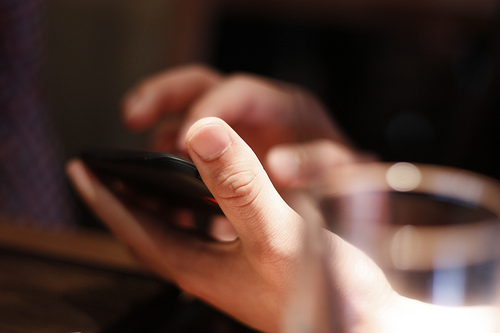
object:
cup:
[283, 159, 497, 329]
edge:
[286, 159, 499, 266]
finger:
[168, 112, 351, 310]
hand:
[62, 115, 499, 332]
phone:
[80, 145, 236, 236]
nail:
[187, 125, 233, 157]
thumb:
[175, 108, 326, 266]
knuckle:
[235, 227, 343, 273]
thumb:
[166, 100, 282, 220]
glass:
[284, 145, 499, 313]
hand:
[48, 106, 498, 332]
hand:
[47, 112, 500, 331]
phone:
[83, 138, 234, 232]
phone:
[82, 127, 252, 240]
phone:
[67, 145, 240, 245]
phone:
[84, 151, 223, 220]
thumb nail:
[185, 127, 235, 161]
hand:
[62, 117, 489, 332]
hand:
[48, 112, 495, 332]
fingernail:
[187, 122, 233, 156]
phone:
[80, 142, 224, 221]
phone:
[81, 122, 241, 251]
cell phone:
[68, 131, 251, 218]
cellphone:
[76, 132, 248, 228]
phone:
[65, 118, 235, 229]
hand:
[57, 115, 482, 332]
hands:
[65, 112, 499, 331]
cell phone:
[63, 127, 253, 252]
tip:
[61, 158, 88, 181]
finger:
[91, 185, 157, 241]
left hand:
[66, 113, 499, 332]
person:
[70, 110, 500, 332]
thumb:
[183, 113, 286, 246]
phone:
[67, 145, 266, 236]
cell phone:
[77, 144, 242, 214]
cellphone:
[78, 135, 229, 212]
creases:
[216, 166, 269, 209]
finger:
[181, 113, 298, 251]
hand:
[60, 103, 499, 331]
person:
[58, 59, 498, 332]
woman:
[66, 65, 499, 332]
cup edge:
[301, 158, 498, 264]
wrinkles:
[212, 163, 263, 212]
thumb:
[181, 113, 298, 254]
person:
[184, 111, 308, 265]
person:
[64, 57, 494, 332]